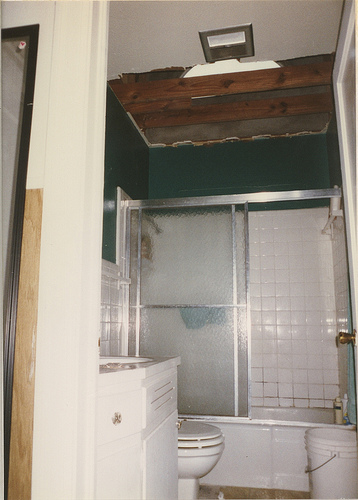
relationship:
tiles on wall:
[245, 208, 345, 409] [148, 133, 343, 411]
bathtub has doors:
[179, 406, 354, 492] [126, 205, 252, 420]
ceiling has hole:
[109, 1, 343, 150] [108, 55, 334, 150]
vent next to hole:
[198, 23, 253, 64] [108, 55, 334, 150]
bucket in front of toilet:
[305, 427, 357, 500] [177, 423, 225, 500]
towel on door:
[179, 306, 230, 330] [126, 205, 252, 420]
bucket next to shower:
[305, 427, 357, 500] [122, 189, 350, 425]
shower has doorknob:
[122, 189, 350, 425] [337, 330, 355, 347]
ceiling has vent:
[109, 1, 343, 150] [198, 23, 253, 64]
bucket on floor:
[305, 427, 357, 500] [200, 484, 304, 499]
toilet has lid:
[177, 423, 225, 500] [178, 421, 222, 440]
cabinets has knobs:
[144, 366, 177, 500] [111, 412, 122, 426]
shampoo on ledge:
[332, 393, 348, 426] [177, 416, 353, 431]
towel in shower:
[179, 306, 230, 330] [122, 189, 350, 425]